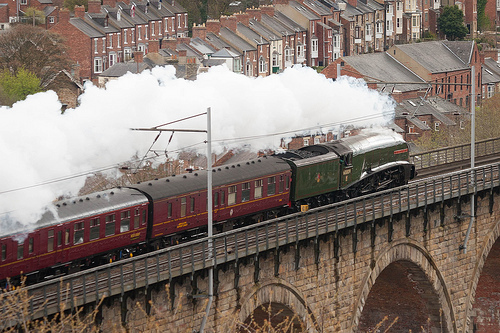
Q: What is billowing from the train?
A: White smoke.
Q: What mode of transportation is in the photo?
A: Train.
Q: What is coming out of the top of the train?
A: Steam.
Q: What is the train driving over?
A: Bridge.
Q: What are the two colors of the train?
A: Green and red.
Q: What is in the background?
A: Houses.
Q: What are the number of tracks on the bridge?
A: 2.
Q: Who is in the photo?
A: No body.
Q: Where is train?
A: On the bridge.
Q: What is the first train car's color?
A: Green.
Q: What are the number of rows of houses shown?
A: 3.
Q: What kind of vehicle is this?
A: Train.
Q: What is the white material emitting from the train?
A: Smoke.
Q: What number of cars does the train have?
A: Two.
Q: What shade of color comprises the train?
A: Red and green.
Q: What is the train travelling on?
A: Train tracks.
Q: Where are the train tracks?
A: Bridge.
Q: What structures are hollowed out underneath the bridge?
A: Tunnels.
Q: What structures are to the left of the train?
A: Buildings.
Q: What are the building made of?
A: Red brick.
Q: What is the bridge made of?
A: Brick.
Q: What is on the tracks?
A: A train.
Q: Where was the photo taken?
A: Outside somewhere.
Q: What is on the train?
A: Windows.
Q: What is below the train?
A: Tracks.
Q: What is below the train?
A: A bridge.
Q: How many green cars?
A: One.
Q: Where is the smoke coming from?
A: The train.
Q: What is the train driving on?
A: A bridge.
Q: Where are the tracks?
A: Under the train.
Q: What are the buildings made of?
A: Brick.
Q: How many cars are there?
A: Three.